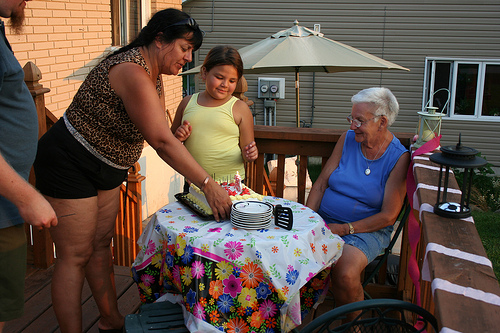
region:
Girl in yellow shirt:
[181, 46, 262, 192]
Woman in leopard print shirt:
[44, 3, 199, 321]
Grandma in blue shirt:
[312, 83, 415, 311]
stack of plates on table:
[230, 195, 274, 234]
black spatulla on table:
[267, 203, 298, 230]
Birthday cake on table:
[174, 168, 268, 220]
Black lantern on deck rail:
[430, 138, 482, 220]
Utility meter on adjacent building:
[253, 71, 290, 124]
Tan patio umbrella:
[192, 3, 412, 125]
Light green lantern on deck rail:
[408, 82, 451, 152]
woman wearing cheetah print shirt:
[52, 20, 210, 176]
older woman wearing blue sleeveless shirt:
[317, 79, 412, 303]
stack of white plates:
[226, 189, 276, 240]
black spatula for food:
[266, 189, 303, 236]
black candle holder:
[428, 133, 484, 228]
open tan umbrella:
[162, 20, 424, 138]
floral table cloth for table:
[131, 172, 323, 332]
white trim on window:
[418, 49, 497, 122]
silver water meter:
[249, 70, 289, 132]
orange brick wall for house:
[31, 7, 115, 158]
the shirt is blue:
[329, 131, 421, 243]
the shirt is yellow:
[176, 99, 268, 189]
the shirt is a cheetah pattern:
[69, 39, 182, 173]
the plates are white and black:
[230, 192, 277, 231]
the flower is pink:
[220, 235, 250, 265]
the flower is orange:
[239, 258, 269, 295]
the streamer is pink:
[401, 212, 440, 323]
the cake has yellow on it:
[177, 164, 272, 249]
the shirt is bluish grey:
[1, 40, 42, 227]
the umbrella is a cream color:
[228, 20, 405, 91]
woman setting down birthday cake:
[32, 7, 234, 332]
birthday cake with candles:
[172, 173, 264, 223]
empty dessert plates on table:
[229, 198, 275, 230]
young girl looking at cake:
[171, 43, 261, 185]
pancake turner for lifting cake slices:
[273, 201, 294, 231]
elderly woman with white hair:
[308, 85, 409, 305]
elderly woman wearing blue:
[306, 87, 418, 332]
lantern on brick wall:
[428, 130, 486, 222]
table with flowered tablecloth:
[131, 193, 343, 331]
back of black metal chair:
[278, 298, 438, 331]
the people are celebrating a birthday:
[50, 1, 418, 330]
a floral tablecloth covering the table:
[160, 233, 312, 331]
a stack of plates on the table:
[226, 197, 273, 239]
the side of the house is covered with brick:
[37, 8, 99, 56]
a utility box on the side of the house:
[253, 74, 291, 126]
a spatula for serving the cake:
[268, 199, 301, 236]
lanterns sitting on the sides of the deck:
[409, 84, 497, 236]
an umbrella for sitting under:
[224, 8, 376, 130]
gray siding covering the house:
[390, 7, 496, 55]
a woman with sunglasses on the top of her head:
[108, 2, 203, 88]